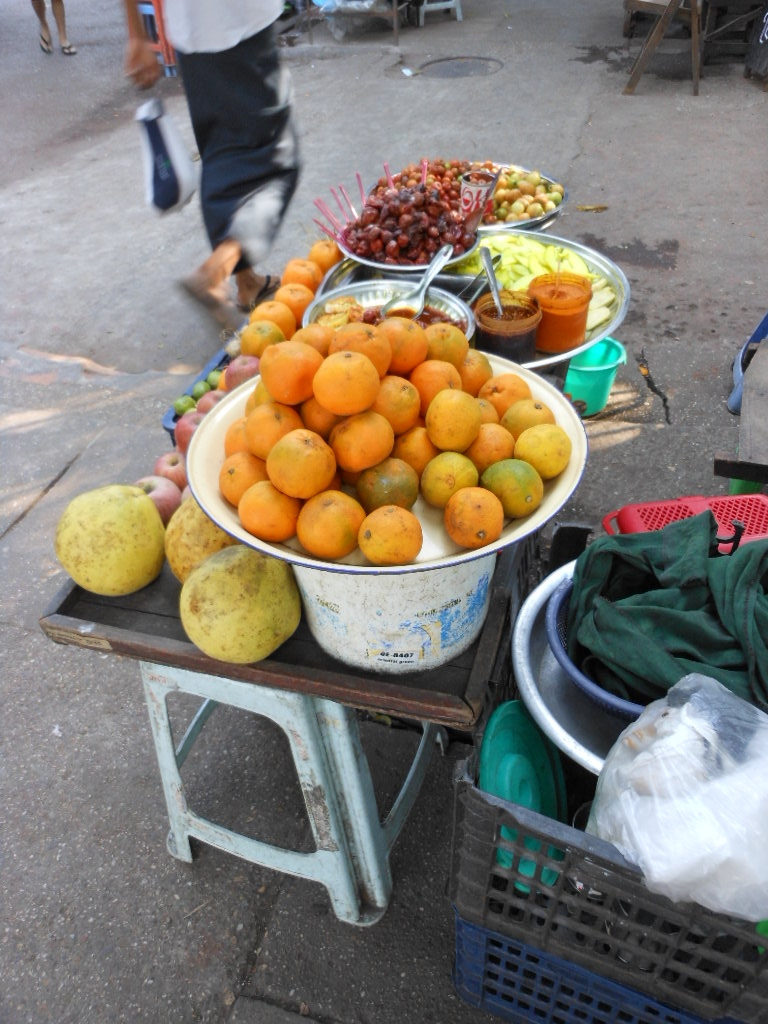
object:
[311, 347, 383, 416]
orange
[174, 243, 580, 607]
display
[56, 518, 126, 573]
crack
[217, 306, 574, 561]
orange fruit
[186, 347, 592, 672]
dish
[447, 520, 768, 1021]
basket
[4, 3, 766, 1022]
pavement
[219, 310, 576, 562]
oranges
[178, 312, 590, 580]
plate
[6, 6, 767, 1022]
sidewalk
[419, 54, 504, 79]
manhole cover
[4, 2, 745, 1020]
street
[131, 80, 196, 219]
bag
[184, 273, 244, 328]
sandal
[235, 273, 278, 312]
sandal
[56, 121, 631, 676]
fruit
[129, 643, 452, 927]
bench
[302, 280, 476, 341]
bowl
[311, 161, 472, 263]
cherries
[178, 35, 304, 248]
skirt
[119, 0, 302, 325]
person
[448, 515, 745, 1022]
crate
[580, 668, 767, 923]
bag